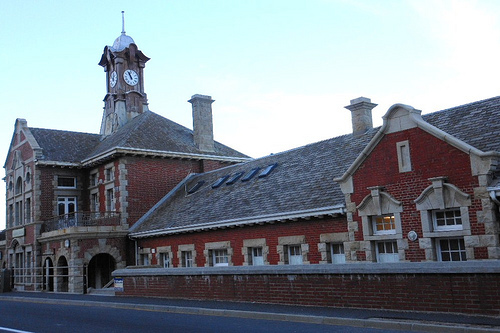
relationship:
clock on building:
[102, 68, 118, 93] [7, 26, 499, 325]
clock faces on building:
[104, 62, 144, 106] [198, 247, 347, 255]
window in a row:
[275, 235, 310, 265] [170, 243, 435, 290]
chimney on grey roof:
[181, 91, 223, 162] [280, 167, 335, 203]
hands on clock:
[132, 60, 140, 129] [103, 70, 148, 95]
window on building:
[435, 237, 462, 260] [156, 97, 497, 257]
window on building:
[371, 213, 394, 233] [156, 97, 497, 257]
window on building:
[372, 240, 401, 261] [156, 97, 497, 257]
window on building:
[432, 208, 459, 230] [156, 97, 497, 257]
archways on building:
[36, 241, 127, 291] [18, 17, 499, 308]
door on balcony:
[55, 192, 76, 223] [48, 205, 127, 238]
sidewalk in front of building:
[7, 288, 497, 331] [7, 26, 499, 325]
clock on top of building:
[96, 67, 156, 92] [0, 11, 497, 328]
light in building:
[368, 209, 417, 232] [120, 90, 497, 330]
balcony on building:
[34, 205, 132, 232] [7, 26, 499, 325]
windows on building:
[134, 217, 396, 285] [136, 79, 488, 257]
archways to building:
[80, 244, 125, 297] [12, 109, 499, 308]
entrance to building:
[49, 253, 82, 290] [12, 109, 499, 308]